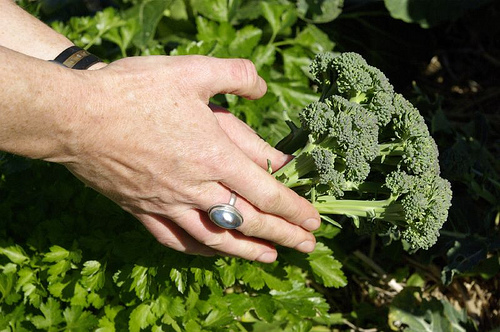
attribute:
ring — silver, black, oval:
[203, 202, 259, 246]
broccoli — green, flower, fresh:
[316, 79, 451, 235]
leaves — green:
[273, 23, 329, 113]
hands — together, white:
[42, 44, 305, 265]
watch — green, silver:
[36, 40, 100, 107]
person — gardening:
[67, 28, 288, 194]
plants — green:
[247, 44, 455, 255]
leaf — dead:
[255, 14, 301, 71]